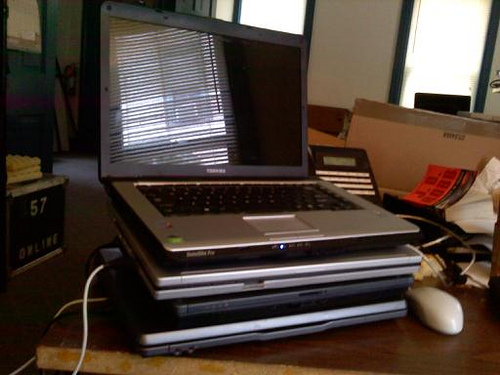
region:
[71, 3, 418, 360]
lap top stacked on other lap tops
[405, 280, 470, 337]
small white computer mouse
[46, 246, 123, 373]
white peripheral cord for computer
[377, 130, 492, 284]
clutter on a computer desk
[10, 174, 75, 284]
an old analog alarm clock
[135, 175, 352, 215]
small onboard keyboard for laptop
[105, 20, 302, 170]
reflection of window and blinds in lcd screen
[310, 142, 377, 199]
part of the control panel for an office phone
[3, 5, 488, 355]
many computers on a cluttered desk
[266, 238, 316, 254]
indication lights for a laptop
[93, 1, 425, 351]
A pike of tablet computers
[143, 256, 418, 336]
A stack of tablet computers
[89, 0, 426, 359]
Stacked laptop computers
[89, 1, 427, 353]
A stack of laptop computers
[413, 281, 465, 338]
A basic white computer mouse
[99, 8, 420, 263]
An open laptop computer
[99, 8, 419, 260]
An open tablet computer with a blank screen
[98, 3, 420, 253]
An open tablet computer reflecting window blinds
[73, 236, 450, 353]
A stack of laptop computers charging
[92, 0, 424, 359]
laptops stacked on each other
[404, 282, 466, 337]
white mouse beside laptops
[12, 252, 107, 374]
cords hanging from laptops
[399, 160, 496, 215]
orange and black book on table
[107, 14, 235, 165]
reflection on the computer screen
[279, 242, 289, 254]
light on the computer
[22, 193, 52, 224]
white numbers on object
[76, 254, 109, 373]
the cord is white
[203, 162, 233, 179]
silver letters on laptop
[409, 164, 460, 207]
black letters on book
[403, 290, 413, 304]
part of a laptop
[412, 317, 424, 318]
part of a mouse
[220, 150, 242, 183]
part of a screen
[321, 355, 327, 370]
part of a table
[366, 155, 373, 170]
part of a laptop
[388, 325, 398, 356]
part of a laptop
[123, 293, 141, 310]
part of a cable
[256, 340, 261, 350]
edge of a laptop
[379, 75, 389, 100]
part of a window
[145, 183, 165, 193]
key on a keyboard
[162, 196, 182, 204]
key on a keyboard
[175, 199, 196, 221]
key on a keyboard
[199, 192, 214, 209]
key on a keyboard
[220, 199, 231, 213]
key on a keyboard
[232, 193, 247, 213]
key on a keyboard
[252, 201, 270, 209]
key on a keyboard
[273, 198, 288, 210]
key on a keyboard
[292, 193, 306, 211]
key on a keyboard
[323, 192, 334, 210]
key on a keyboard